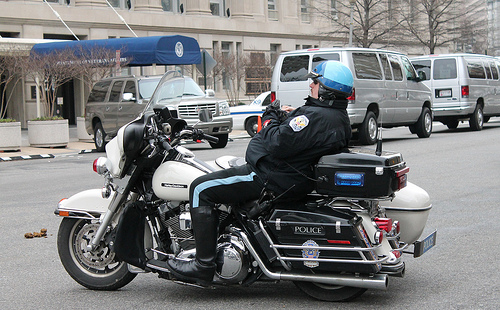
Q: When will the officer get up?
A: After he is finished taking a break.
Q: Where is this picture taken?
A: On a road.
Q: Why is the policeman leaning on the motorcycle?
A: Because he is tired.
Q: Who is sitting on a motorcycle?
A: A policeman.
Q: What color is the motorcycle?
A: Black and white.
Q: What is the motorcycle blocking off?
A: A road.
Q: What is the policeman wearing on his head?
A: A helmet.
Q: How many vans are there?
A: Two.